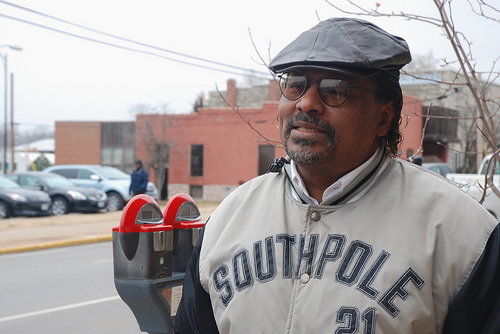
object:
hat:
[267, 16, 413, 79]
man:
[171, 17, 499, 334]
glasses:
[278, 70, 375, 108]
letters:
[376, 266, 426, 318]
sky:
[0, 0, 500, 132]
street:
[0, 240, 143, 334]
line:
[0, 296, 121, 324]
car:
[44, 164, 159, 212]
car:
[4, 171, 110, 215]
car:
[0, 173, 53, 217]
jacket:
[170, 141, 500, 334]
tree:
[333, 0, 500, 201]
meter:
[112, 193, 175, 280]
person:
[128, 159, 149, 197]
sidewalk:
[0, 198, 222, 256]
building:
[208, 69, 499, 171]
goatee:
[283, 111, 336, 167]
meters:
[163, 191, 205, 274]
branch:
[400, 70, 470, 87]